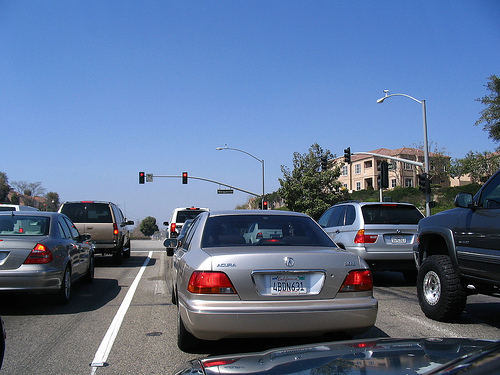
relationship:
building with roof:
[319, 146, 438, 189] [347, 151, 431, 156]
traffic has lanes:
[1, 144, 484, 373] [6, 151, 498, 371]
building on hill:
[319, 137, 438, 189] [356, 190, 436, 200]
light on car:
[186, 269, 238, 294] [162, 209, 381, 351]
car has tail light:
[162, 209, 381, 351] [340, 270, 373, 293]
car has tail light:
[162, 209, 381, 351] [188, 270, 233, 292]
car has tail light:
[0, 210, 97, 302] [112, 224, 122, 236]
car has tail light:
[0, 210, 97, 302] [352, 229, 382, 244]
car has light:
[0, 210, 97, 302] [21, 240, 52, 264]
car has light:
[0, 210, 97, 302] [194, 256, 271, 326]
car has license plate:
[162, 209, 381, 351] [270, 277, 309, 299]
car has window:
[162, 209, 381, 351] [203, 216, 330, 247]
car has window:
[162, 209, 381, 351] [184, 211, 354, 267]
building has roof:
[319, 146, 438, 189] [370, 147, 427, 162]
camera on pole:
[382, 85, 389, 97] [392, 88, 432, 195]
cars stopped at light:
[98, 190, 419, 370] [134, 147, 292, 195]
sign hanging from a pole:
[215, 188, 233, 193] [229, 177, 264, 200]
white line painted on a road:
[91, 249, 154, 374] [1, 239, 498, 374]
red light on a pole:
[139, 172, 144, 174] [132, 141, 269, 208]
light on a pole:
[182, 172, 188, 177] [322, 87, 437, 202]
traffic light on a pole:
[257, 194, 271, 208] [322, 87, 437, 202]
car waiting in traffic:
[162, 209, 381, 351] [1, 144, 484, 373]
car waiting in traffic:
[416, 202, 483, 286] [1, 144, 484, 373]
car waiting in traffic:
[0, 210, 97, 302] [1, 144, 484, 373]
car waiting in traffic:
[86, 197, 128, 250] [1, 144, 484, 373]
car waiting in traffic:
[411, 166, 499, 323] [0, 166, 484, 370]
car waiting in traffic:
[53, 200, 135, 265] [1, 144, 484, 373]